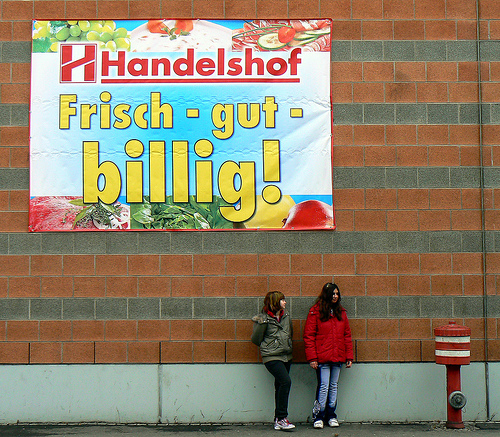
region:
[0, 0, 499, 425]
a brick building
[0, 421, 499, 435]
an asphalt ground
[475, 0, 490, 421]
a seam in the building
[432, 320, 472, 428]
a red and white fire hydrant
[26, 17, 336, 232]
an advertising banner on the building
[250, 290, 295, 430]
a girl standing on the left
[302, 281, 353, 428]
a girl standing on the right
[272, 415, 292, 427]
the left girl's tennis shoe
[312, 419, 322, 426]
the right girl's tennis shoe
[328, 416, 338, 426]
the right girl's tennis shoe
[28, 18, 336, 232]
large banner hanging on a wall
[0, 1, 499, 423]
brick wall behind banner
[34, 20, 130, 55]
image of grapes on banner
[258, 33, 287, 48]
cucumber slice printed on banner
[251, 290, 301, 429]
girl leaning against wall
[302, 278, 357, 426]
girl standing next to girl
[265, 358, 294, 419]
girl wearing black pants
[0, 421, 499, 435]
gray sidewalk beneath girl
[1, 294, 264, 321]
line of gray bricks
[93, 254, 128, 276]
brick next to brick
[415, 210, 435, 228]
part of a brick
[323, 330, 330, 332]
part of a jacket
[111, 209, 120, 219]
part of a board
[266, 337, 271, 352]
part of a jacket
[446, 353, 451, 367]
part of a pole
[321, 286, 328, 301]
hair of a lady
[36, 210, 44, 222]
edge of a board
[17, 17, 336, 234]
an advertisement on a brick building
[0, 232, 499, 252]
a row of gray bricks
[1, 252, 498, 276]
a row of red bricks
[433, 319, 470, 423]
a red, white, and gray hydrant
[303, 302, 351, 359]
a red puffer jacket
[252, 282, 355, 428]
two women in front of a brick building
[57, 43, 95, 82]
a logo for Handelshof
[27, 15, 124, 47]
a picture of grapes on the advertisement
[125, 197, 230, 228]
a picture of spinach on the advertisment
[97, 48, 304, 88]
the name of a company underlined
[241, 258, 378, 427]
Two girls standing in front of a building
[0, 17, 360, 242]
large banner on the building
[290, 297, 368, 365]
Red jack on the girl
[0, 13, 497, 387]
Brick made of concrete block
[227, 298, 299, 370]
Green jacket on the girl on the left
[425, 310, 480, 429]
Red and white fire hydrant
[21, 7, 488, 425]
Photo taken during the day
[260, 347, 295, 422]
Black pants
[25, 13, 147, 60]
Grapes on the banner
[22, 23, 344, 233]
Banner words are German